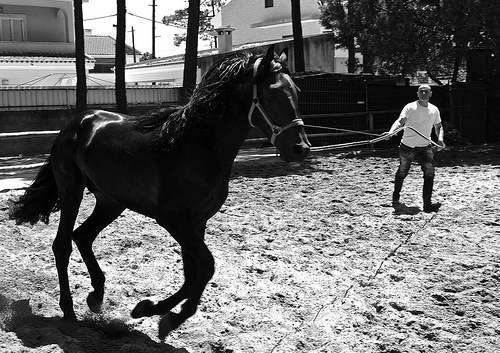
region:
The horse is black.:
[12, 43, 323, 351]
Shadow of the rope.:
[273, 198, 461, 332]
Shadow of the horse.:
[1, 307, 134, 351]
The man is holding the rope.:
[291, 106, 443, 148]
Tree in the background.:
[340, 3, 499, 66]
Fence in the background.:
[0, 87, 400, 157]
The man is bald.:
[410, 79, 438, 100]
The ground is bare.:
[364, 255, 491, 351]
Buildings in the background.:
[8, 7, 187, 144]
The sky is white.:
[87, 2, 204, 64]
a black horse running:
[23, 20, 348, 348]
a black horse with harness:
[30, 46, 314, 335]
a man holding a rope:
[373, 80, 492, 255]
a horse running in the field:
[19, 40, 344, 352]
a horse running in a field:
[34, 17, 361, 352]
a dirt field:
[261, 182, 456, 342]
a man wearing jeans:
[348, 27, 483, 237]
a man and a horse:
[40, 35, 456, 301]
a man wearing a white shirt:
[371, 67, 471, 212]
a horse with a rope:
[8, 42, 474, 304]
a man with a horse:
[18, 28, 468, 348]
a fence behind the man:
[6, 66, 496, 171]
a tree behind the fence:
[307, 2, 498, 158]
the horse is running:
[14, 40, 324, 330]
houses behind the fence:
[3, 3, 495, 147]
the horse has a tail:
[6, 104, 101, 266]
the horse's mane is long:
[121, 32, 321, 192]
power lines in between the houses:
[77, 0, 202, 80]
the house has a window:
[1, 7, 95, 84]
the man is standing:
[368, 55, 463, 225]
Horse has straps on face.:
[246, 60, 324, 199]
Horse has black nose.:
[273, 115, 320, 189]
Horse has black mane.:
[151, 72, 251, 138]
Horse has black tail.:
[9, 165, 80, 238]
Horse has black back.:
[76, 103, 208, 245]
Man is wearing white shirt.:
[403, 99, 448, 174]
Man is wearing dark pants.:
[386, 140, 433, 192]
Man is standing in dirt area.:
[363, 188, 478, 268]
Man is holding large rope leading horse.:
[338, 96, 445, 179]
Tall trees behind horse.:
[22, 12, 282, 124]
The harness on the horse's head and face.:
[247, 55, 327, 160]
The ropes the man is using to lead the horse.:
[301, 105, 433, 155]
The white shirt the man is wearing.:
[395, 95, 440, 146]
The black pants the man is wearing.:
[390, 140, 440, 205]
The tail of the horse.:
[15, 150, 70, 220]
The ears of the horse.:
[245, 32, 295, 72]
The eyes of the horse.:
[265, 80, 305, 101]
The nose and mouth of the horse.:
[280, 131, 310, 172]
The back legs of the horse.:
[58, 192, 108, 348]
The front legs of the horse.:
[133, 210, 222, 342]